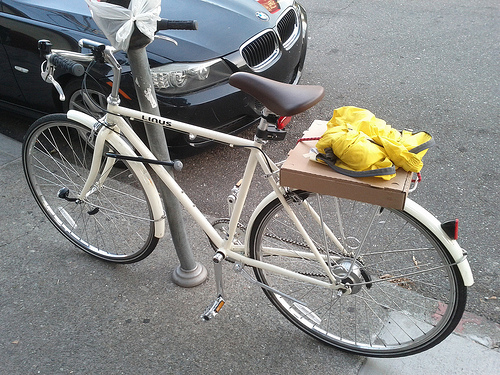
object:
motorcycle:
[8, 36, 472, 367]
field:
[8, 141, 468, 371]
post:
[21, 158, 490, 370]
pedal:
[183, 284, 239, 327]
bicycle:
[34, 0, 482, 351]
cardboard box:
[282, 103, 434, 212]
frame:
[104, 100, 275, 288]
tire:
[21, 113, 158, 262]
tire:
[248, 182, 472, 357]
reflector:
[441, 216, 457, 239]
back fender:
[405, 201, 477, 289]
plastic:
[80, 0, 165, 52]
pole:
[96, 0, 208, 289]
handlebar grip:
[40, 45, 87, 105]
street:
[17, 2, 498, 340]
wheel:
[247, 177, 465, 352]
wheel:
[18, 112, 162, 266]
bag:
[306, 103, 432, 180]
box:
[277, 99, 435, 210]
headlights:
[142, 54, 241, 96]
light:
[441, 217, 460, 239]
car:
[0, 0, 312, 159]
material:
[313, 103, 435, 180]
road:
[201, 50, 466, 223]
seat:
[229, 71, 327, 118]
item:
[307, 89, 438, 184]